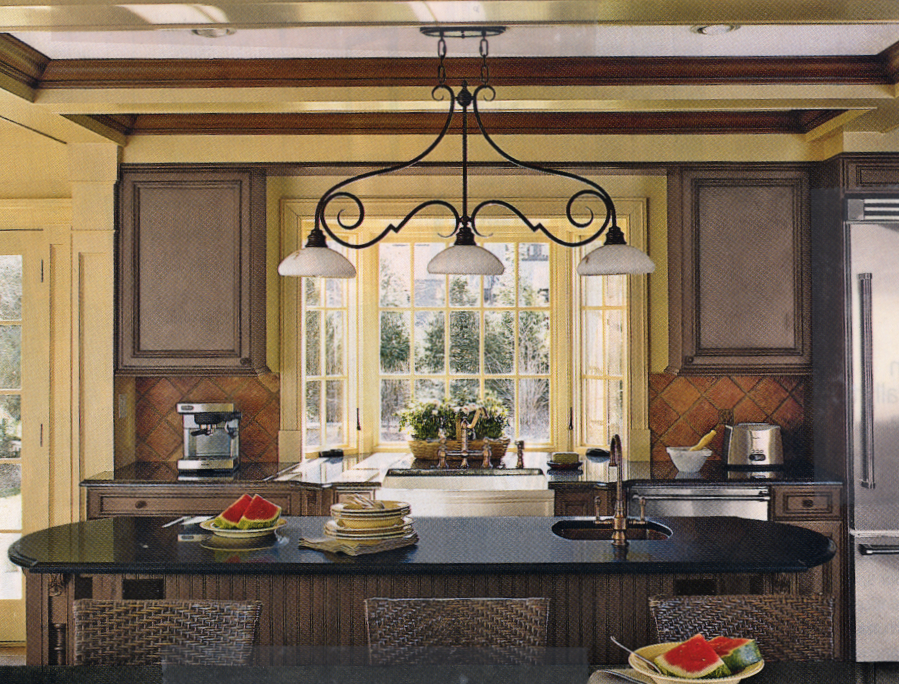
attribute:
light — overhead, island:
[274, 9, 658, 274]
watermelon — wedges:
[654, 626, 761, 681]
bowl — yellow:
[620, 621, 767, 680]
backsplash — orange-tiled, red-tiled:
[131, 363, 281, 469]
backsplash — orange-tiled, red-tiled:
[644, 359, 807, 472]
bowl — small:
[663, 445, 715, 475]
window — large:
[290, 206, 632, 469]